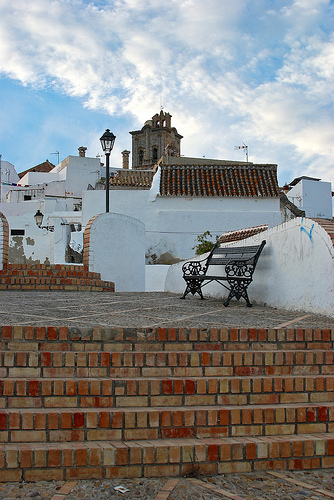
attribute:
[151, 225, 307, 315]
bench — black, nice, metal, designed, ornate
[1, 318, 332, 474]
steps — brick, set, dark, brown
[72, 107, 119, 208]
post — black, protruding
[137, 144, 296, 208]
roof — tiled, tile, multicolored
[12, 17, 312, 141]
sky — blue, bright, cloudy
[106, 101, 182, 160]
chimney — present, brick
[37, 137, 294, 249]
building — nice, stone, tall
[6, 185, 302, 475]
staircase — red, brick, curved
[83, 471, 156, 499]
trash — white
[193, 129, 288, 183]
antenna — metal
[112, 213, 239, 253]
paint — peeling, chipped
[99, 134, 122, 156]
light — glass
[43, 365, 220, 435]
bricks — dark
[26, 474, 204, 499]
ground — cobblestone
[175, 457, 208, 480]
grass — brown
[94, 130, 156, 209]
lamp — black, gas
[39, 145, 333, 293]
buildings — grouped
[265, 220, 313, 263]
paint — blue